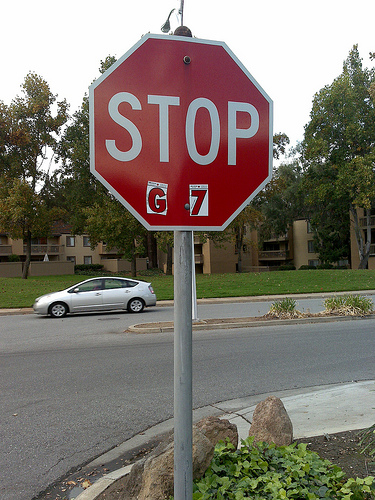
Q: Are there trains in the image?
A: No, there are no trains.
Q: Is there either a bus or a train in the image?
A: No, there are no trains or buses.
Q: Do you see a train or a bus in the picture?
A: No, there are no trains or buses.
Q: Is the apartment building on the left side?
A: Yes, the apartment building is on the left of the image.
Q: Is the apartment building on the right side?
A: No, the apartment building is on the left of the image.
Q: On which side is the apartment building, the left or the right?
A: The apartment building is on the left of the image.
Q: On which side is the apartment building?
A: The apartment building is on the left of the image.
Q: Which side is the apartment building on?
A: The apartment building is on the left of the image.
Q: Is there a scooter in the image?
A: No, there are no scooters.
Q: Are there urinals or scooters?
A: No, there are no scooters or urinals.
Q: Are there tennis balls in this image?
A: No, there are no tennis balls.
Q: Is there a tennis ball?
A: No, there are no tennis balls.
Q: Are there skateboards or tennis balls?
A: No, there are no tennis balls or skateboards.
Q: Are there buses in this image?
A: No, there are no buses.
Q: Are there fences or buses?
A: No, there are no buses or fences.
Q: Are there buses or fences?
A: No, there are no buses or fences.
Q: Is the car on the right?
A: No, the car is on the left of the image.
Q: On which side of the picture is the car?
A: The car is on the left of the image.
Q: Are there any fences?
A: No, there are no fences.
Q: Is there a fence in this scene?
A: No, there are no fences.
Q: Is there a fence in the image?
A: No, there are no fences.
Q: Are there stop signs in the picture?
A: Yes, there is a stop sign.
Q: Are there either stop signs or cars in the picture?
A: Yes, there is a stop sign.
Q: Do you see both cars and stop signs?
A: Yes, there are both a stop sign and a car.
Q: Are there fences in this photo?
A: No, there are no fences.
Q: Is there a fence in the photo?
A: No, there are no fences.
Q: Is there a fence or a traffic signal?
A: No, there are no fences or traffic lights.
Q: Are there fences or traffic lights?
A: No, there are no fences or traffic lights.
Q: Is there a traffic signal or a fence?
A: No, there are no fences or traffic lights.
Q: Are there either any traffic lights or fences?
A: No, there are no fences or traffic lights.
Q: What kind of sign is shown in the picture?
A: The sign is a stop sign.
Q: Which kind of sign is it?
A: The sign is a stop sign.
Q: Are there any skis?
A: No, there are no skis.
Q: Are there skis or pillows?
A: No, there are no skis or pillows.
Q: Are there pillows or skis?
A: No, there are no skis or pillows.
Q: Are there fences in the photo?
A: No, there are no fences.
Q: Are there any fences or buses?
A: No, there are no fences or buses.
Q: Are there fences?
A: No, there are no fences.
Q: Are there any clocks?
A: No, there are no clocks.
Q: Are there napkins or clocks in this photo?
A: No, there are no clocks or napkins.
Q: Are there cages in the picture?
A: No, there are no cages.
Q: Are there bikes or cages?
A: No, there are no cages or bikes.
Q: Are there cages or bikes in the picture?
A: No, there are no cages or bikes.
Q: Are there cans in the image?
A: No, there are no cans.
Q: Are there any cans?
A: No, there are no cans.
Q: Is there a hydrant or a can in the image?
A: No, there are no cans or fire hydrants.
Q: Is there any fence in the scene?
A: No, there are no fences.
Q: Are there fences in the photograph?
A: No, there are no fences.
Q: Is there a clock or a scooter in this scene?
A: No, there are no clocks or scooters.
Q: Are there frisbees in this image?
A: No, there are no frisbees.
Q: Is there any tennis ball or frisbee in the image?
A: No, there are no frisbees or tennis balls.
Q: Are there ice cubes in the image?
A: No, there are no ice cubes.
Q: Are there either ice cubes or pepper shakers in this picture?
A: No, there are no ice cubes or pepper shakers.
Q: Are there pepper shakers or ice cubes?
A: No, there are no ice cubes or pepper shakers.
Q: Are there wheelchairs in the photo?
A: No, there are no wheelchairs.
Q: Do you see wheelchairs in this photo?
A: No, there are no wheelchairs.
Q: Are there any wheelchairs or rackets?
A: No, there are no wheelchairs or rackets.